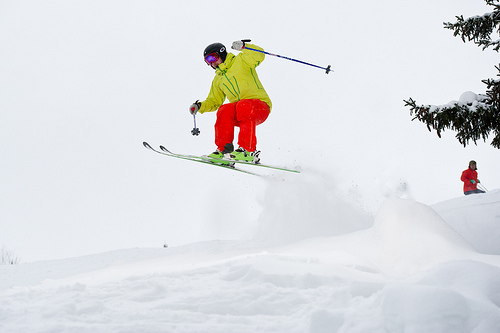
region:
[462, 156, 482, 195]
the man is watching the skier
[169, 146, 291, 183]
the skis are green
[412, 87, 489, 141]
snow is on the tree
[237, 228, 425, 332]
there is snow on the ground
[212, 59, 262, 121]
the girls jacket is yellow and green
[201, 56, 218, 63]
the girl is wearing goggles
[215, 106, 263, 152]
the girl is wearing red pants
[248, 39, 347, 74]
the girl is holding ski poles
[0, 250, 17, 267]
there are trees in the distance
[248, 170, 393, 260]
there is a mountain of snow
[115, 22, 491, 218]
skier jumping while being watched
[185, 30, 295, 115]
skier wearing yellow jacket with green lines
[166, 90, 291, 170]
bent legs in orange pants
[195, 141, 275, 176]
lime-green boots on feet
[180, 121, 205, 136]
six prongs at end of ski pole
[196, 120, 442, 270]
lifted snow behind skis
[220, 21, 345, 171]
pole parallel with ski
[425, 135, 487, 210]
onlooker dressed in orange jacket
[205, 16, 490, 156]
tips of evergreen branches pointed at skier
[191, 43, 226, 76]
goggles rimmed in red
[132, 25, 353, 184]
skier jumping in the air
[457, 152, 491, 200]
person watching jumping skier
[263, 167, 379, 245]
snow kicked up by skis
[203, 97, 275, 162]
orange pants on skier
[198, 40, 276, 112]
yellow jacket on skier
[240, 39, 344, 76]
pole in skier's hand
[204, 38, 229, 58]
black helmet on head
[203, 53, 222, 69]
goggles on skier's face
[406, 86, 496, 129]
snow on evergreen branch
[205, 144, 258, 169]
yellow boots on skis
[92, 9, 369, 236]
a skiier in the air mid jump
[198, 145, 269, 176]
neon green ski boots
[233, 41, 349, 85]
one black ski pole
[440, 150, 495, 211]
a skier in a red jacket and balck hat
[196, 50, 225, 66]
red and purple ski goggles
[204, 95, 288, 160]
neon orange ski pants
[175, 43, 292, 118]
a bright yellow and green ski jacket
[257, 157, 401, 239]
powdered white snow flying into the air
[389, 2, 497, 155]
two evergreen tree branches with snow on top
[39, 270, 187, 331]
lumpy white snow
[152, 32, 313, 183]
a man jumping in the air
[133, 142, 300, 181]
the skiis on the mans feet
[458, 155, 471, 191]
a person standing on the mountain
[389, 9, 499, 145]
a tree on the side of the hill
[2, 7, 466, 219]
the grey sky above the mountain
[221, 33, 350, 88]
a ski pole the man is holding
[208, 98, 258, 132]
the man's red pants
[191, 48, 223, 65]
the goggles on the man's head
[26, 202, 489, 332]
the snow on the mountain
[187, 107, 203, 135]
the other ski pole